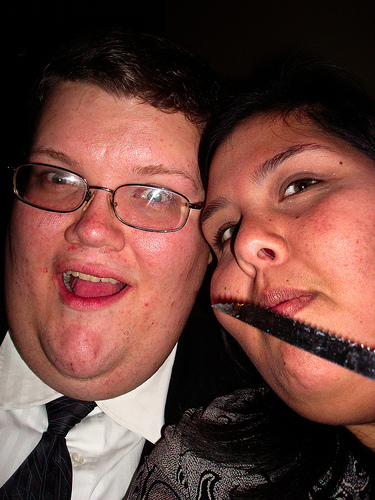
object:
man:
[0, 32, 226, 498]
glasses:
[7, 163, 206, 232]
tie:
[0, 396, 96, 499]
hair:
[35, 22, 231, 137]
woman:
[124, 72, 374, 500]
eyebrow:
[249, 141, 337, 188]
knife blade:
[210, 302, 375, 382]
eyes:
[283, 178, 322, 199]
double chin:
[3, 311, 180, 404]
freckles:
[310, 225, 374, 273]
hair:
[199, 69, 375, 196]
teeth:
[89, 275, 100, 282]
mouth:
[52, 259, 136, 312]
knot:
[43, 396, 95, 437]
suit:
[0, 330, 218, 498]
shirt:
[0, 334, 182, 499]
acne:
[65, 243, 84, 255]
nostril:
[257, 246, 274, 260]